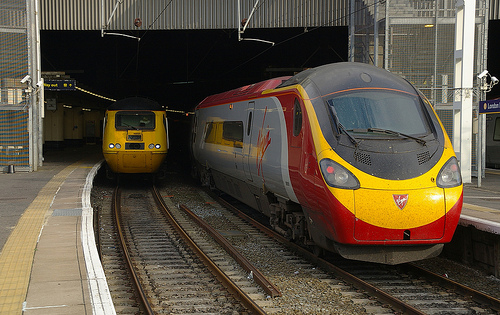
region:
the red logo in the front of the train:
[383, 189, 428, 214]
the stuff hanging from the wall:
[70, 6, 150, 46]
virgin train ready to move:
[217, 91, 299, 184]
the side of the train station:
[30, 163, 68, 289]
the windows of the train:
[309, 83, 456, 159]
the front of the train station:
[318, 57, 425, 234]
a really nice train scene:
[13, 71, 488, 288]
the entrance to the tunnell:
[18, 93, 75, 187]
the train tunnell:
[78, 38, 243, 90]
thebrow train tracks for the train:
[103, 206, 286, 313]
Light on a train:
[99, 141, 132, 148]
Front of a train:
[101, 105, 182, 171]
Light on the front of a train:
[306, 145, 365, 202]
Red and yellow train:
[278, 78, 479, 268]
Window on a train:
[293, 78, 433, 170]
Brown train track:
[103, 199, 219, 314]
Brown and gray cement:
[18, 169, 82, 245]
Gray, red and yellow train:
[198, 84, 362, 217]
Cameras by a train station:
[21, 71, 65, 112]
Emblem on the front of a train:
[391, 196, 417, 210]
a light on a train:
[103, 138, 118, 151]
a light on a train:
[113, 140, 124, 152]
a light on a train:
[143, 137, 156, 152]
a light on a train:
[153, 142, 163, 152]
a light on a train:
[128, 132, 143, 142]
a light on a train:
[321, 162, 333, 177]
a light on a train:
[334, 166, 350, 186]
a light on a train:
[443, 170, 457, 184]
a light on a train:
[449, 159, 457, 171]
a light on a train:
[450, 170, 465, 180]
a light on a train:
[108, 140, 116, 153]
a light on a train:
[126, 127, 146, 145]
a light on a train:
[330, 170, 356, 188]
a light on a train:
[360, 67, 376, 84]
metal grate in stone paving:
[51, 206, 81, 220]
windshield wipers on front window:
[344, 126, 429, 146]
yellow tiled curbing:
[1, 161, 79, 313]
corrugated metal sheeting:
[40, 0, 351, 29]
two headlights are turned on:
[106, 141, 162, 151]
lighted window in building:
[6, 85, 26, 107]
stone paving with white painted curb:
[22, 163, 116, 313]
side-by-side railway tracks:
[111, 166, 499, 314]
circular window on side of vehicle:
[288, 92, 304, 139]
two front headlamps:
[317, 154, 463, 190]